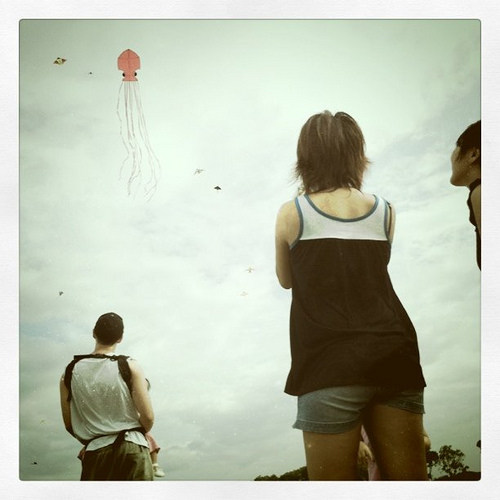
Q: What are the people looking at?
A: Kite.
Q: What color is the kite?
A: Pink.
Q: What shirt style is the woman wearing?
A: Tank top.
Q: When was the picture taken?
A: Daytime.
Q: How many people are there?
A: Three.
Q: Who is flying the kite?
A: The man.